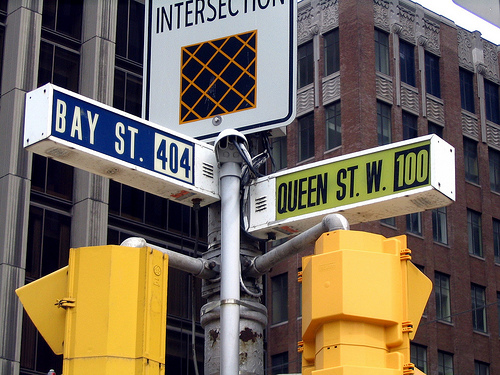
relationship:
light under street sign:
[296, 229, 433, 375] [240, 132, 458, 239]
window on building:
[468, 212, 487, 258] [269, 1, 496, 372]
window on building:
[391, 36, 428, 94] [269, 1, 496, 372]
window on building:
[424, 47, 444, 98] [243, 0, 498, 373]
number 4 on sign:
[150, 130, 168, 186] [50, 89, 193, 188]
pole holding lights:
[182, 132, 261, 374] [26, 232, 426, 368]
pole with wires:
[218, 164, 241, 374] [230, 139, 267, 181]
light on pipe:
[296, 225, 438, 373] [119, 127, 354, 374]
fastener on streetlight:
[53, 278, 86, 325] [11, 219, 223, 374]